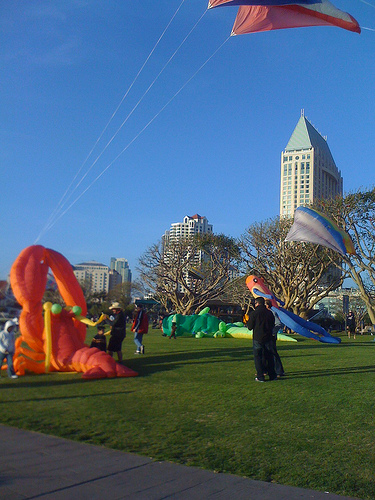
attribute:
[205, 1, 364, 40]
kite — colorful, red, large, white, green, & yellow, gray, blue, orange, & blue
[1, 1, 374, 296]
sky — blue, clear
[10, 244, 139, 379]
balloon — large, lobster, orange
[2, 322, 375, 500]
grass — short, lush, green, dark green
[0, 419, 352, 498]
sidewalk — cement, paved, dark gray, gray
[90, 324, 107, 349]
person — child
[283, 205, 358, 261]
balloon — flying, gray, white, blue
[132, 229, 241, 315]
tree — bare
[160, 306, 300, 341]
balloon — large, green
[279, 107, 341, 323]
building — tall, blue, white, teal, green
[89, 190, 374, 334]
trees — lined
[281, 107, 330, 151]
tower — green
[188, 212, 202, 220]
roof — red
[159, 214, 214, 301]
building — round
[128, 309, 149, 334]
coat — red, black, & gray, orange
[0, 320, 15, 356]
jacket — gray